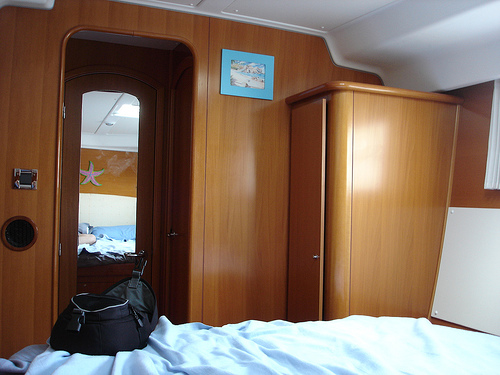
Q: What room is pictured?
A: It is a bedroom.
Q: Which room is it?
A: It is a bedroom.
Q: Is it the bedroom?
A: Yes, it is the bedroom.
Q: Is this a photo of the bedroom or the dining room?
A: It is showing the bedroom.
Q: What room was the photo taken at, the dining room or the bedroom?
A: It was taken at the bedroom.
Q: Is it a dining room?
A: No, it is a bedroom.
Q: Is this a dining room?
A: No, it is a bedroom.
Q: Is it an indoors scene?
A: Yes, it is indoors.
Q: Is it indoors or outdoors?
A: It is indoors.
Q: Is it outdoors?
A: No, it is indoors.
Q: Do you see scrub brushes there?
A: No, there are no scrub brushes.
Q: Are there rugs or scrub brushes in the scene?
A: No, there are no scrub brushes or rugs.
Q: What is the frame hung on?
A: The frame is hung on the wall.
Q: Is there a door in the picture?
A: Yes, there is a door.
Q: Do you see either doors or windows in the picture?
A: Yes, there is a door.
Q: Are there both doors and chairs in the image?
A: No, there is a door but no chairs.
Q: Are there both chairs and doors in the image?
A: No, there is a door but no chairs.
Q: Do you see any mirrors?
A: Yes, there is a mirror.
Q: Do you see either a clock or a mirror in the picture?
A: Yes, there is a mirror.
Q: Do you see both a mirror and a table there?
A: No, there is a mirror but no tables.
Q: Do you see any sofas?
A: No, there are no sofas.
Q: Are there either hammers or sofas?
A: No, there are no sofas or hammers.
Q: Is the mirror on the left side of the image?
A: Yes, the mirror is on the left of the image.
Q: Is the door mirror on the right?
A: No, the mirror is on the left of the image.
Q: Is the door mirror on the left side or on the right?
A: The mirror is on the left of the image.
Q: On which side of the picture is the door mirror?
A: The mirror is on the left of the image.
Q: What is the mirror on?
A: The mirror is on the door.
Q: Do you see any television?
A: No, there are no televisions.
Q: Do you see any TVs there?
A: No, there are no tvs.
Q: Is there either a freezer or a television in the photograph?
A: No, there are no televisions or refrigerators.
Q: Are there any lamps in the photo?
A: No, there are no lamps.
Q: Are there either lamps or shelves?
A: No, there are no lamps or shelves.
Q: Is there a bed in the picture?
A: Yes, there is a bed.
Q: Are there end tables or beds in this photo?
A: Yes, there is a bed.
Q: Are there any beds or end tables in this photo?
A: Yes, there is a bed.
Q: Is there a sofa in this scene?
A: No, there are no sofas.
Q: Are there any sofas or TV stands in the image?
A: No, there are no sofas or TV stands.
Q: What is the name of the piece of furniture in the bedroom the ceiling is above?
A: The piece of furniture is a bed.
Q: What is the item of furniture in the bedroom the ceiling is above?
A: The piece of furniture is a bed.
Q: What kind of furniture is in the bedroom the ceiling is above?
A: The piece of furniture is a bed.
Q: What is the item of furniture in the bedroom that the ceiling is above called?
A: The piece of furniture is a bed.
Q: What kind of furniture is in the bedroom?
A: The piece of furniture is a bed.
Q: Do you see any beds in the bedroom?
A: Yes, there is a bed in the bedroom.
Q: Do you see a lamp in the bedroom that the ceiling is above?
A: No, there is a bed in the bedroom.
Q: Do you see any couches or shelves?
A: No, there are no shelves or couches.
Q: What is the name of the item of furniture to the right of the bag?
A: The piece of furniture is a closet.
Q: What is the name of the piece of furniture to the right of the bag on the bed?
A: The piece of furniture is a closet.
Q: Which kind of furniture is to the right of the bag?
A: The piece of furniture is a closet.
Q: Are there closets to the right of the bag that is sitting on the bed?
A: Yes, there is a closet to the right of the bag.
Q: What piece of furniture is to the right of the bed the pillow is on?
A: The piece of furniture is a closet.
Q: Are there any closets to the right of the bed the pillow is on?
A: Yes, there is a closet to the right of the bed.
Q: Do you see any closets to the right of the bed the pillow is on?
A: Yes, there is a closet to the right of the bed.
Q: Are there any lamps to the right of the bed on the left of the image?
A: No, there is a closet to the right of the bed.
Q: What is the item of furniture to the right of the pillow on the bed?
A: The piece of furniture is a closet.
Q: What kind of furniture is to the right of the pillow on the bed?
A: The piece of furniture is a closet.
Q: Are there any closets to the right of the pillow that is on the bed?
A: Yes, there is a closet to the right of the pillow.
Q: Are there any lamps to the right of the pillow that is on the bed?
A: No, there is a closet to the right of the pillow.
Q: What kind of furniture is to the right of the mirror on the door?
A: The piece of furniture is a closet.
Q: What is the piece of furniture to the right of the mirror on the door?
A: The piece of furniture is a closet.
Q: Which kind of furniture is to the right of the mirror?
A: The piece of furniture is a closet.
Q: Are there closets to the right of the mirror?
A: Yes, there is a closet to the right of the mirror.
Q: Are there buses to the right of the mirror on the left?
A: No, there is a closet to the right of the mirror.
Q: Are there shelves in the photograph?
A: No, there are no shelves.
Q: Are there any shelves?
A: No, there are no shelves.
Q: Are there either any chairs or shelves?
A: No, there are no shelves or chairs.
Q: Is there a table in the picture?
A: No, there are no tables.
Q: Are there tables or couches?
A: No, there are no tables or couches.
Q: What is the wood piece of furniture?
A: The piece of furniture is a closet.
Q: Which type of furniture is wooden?
A: The furniture is a closet.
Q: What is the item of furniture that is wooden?
A: The piece of furniture is a closet.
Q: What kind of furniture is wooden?
A: The furniture is a closet.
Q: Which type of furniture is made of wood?
A: The furniture is a closet.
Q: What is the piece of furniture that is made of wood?
A: The piece of furniture is a closet.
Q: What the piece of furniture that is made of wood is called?
A: The piece of furniture is a closet.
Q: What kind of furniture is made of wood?
A: The furniture is a closet.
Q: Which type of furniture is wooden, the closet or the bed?
A: The closet is wooden.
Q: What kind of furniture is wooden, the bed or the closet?
A: The closet is wooden.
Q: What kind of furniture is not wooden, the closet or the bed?
A: The bed is not wooden.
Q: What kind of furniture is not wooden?
A: The furniture is a bed.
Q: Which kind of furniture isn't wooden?
A: The furniture is a bed.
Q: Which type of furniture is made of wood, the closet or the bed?
A: The closet is made of wood.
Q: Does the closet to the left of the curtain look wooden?
A: Yes, the closet is wooden.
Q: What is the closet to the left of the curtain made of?
A: The closet is made of wood.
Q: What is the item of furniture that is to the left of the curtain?
A: The piece of furniture is a closet.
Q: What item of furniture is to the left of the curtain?
A: The piece of furniture is a closet.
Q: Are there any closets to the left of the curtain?
A: Yes, there is a closet to the left of the curtain.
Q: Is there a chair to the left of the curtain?
A: No, there is a closet to the left of the curtain.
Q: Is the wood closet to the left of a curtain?
A: Yes, the closet is to the left of a curtain.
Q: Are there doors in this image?
A: Yes, there is a door.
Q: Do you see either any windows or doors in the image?
A: Yes, there is a door.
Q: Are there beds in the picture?
A: Yes, there is a bed.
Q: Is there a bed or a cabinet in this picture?
A: Yes, there is a bed.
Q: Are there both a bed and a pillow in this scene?
A: Yes, there are both a bed and a pillow.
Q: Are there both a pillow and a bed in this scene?
A: Yes, there are both a bed and a pillow.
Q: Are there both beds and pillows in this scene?
A: Yes, there are both a bed and a pillow.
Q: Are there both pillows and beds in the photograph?
A: Yes, there are both a bed and a pillow.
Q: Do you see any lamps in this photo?
A: No, there are no lamps.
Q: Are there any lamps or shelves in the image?
A: No, there are no lamps or shelves.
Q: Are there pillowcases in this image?
A: No, there are no pillowcases.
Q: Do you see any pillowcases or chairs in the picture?
A: No, there are no pillowcases or chairs.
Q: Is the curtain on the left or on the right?
A: The curtain is on the right of the image.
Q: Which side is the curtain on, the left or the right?
A: The curtain is on the right of the image.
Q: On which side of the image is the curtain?
A: The curtain is on the right of the image.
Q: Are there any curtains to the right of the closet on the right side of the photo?
A: Yes, there is a curtain to the right of the closet.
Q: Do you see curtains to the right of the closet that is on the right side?
A: Yes, there is a curtain to the right of the closet.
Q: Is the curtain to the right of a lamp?
A: No, the curtain is to the right of the closet.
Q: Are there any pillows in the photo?
A: Yes, there is a pillow.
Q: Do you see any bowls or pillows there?
A: Yes, there is a pillow.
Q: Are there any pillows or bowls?
A: Yes, there is a pillow.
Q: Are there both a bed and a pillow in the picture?
A: Yes, there are both a pillow and a bed.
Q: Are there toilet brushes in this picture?
A: No, there are no toilet brushes.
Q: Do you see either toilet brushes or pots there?
A: No, there are no toilet brushes or pots.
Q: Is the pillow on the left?
A: Yes, the pillow is on the left of the image.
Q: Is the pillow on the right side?
A: No, the pillow is on the left of the image.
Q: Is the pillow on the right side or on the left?
A: The pillow is on the left of the image.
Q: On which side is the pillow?
A: The pillow is on the left of the image.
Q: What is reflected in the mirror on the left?
A: The pillow is reflected in the mirror.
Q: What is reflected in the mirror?
A: The pillow is reflected in the mirror.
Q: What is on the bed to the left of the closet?
A: The pillow is on the bed.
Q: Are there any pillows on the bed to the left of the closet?
A: Yes, there is a pillow on the bed.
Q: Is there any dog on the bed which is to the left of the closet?
A: No, there is a pillow on the bed.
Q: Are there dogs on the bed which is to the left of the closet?
A: No, there is a pillow on the bed.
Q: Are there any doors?
A: Yes, there is a door.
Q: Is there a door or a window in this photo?
A: Yes, there is a door.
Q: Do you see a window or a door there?
A: Yes, there is a door.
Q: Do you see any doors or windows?
A: Yes, there is a door.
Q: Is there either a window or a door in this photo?
A: Yes, there is a door.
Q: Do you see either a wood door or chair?
A: Yes, there is a wood door.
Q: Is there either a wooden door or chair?
A: Yes, there is a wood door.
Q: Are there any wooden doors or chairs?
A: Yes, there is a wood door.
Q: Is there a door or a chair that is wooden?
A: Yes, the door is wooden.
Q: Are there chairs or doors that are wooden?
A: Yes, the door is wooden.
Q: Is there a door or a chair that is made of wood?
A: Yes, the door is made of wood.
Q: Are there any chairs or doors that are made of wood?
A: Yes, the door is made of wood.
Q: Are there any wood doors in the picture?
A: Yes, there is a wood door.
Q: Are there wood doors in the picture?
A: Yes, there is a wood door.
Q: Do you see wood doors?
A: Yes, there is a wood door.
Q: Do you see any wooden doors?
A: Yes, there is a wood door.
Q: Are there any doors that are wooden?
A: Yes, there is a door that is wooden.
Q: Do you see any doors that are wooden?
A: Yes, there is a door that is wooden.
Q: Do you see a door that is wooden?
A: Yes, there is a door that is wooden.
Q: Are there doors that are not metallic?
A: Yes, there is a wooden door.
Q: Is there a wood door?
A: Yes, there is a door that is made of wood.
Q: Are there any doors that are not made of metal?
A: Yes, there is a door that is made of wood.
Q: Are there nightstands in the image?
A: No, there are no nightstands.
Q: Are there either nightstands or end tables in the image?
A: No, there are no nightstands or end tables.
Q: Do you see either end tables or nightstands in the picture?
A: No, there are no nightstands or end tables.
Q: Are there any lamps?
A: No, there are no lamps.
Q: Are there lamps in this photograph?
A: No, there are no lamps.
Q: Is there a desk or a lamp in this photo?
A: No, there are no lamps or desks.